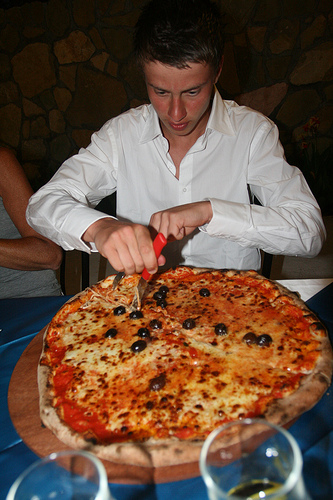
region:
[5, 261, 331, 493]
large pizza with olives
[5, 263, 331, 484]
pizza on wooden serving tray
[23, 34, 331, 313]
young man cutting up pizza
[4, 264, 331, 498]
pizza resting on table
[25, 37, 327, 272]
man wearing white shirt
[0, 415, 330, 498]
glasses on table with blue tablecloth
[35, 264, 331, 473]
thick crust pizza with olives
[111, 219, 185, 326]
knife cutting into pizza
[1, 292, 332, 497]
blue tablecloth on table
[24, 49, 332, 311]
man staring at pizza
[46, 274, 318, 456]
cooked pizza on board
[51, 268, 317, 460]
cheese and olive pizza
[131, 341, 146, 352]
black olive on pizza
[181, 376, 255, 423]
melted cheese on piza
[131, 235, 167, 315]
red plastic and metal knife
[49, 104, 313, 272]
white button down shirt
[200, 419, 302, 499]
glass of wine on table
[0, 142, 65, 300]
person sitting on chair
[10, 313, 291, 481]
brown wooden pizza board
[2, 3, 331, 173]
brown stone covered wall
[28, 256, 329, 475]
a big . yummy pizza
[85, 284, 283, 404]
it has black olives on it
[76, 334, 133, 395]
it also has lots of cheese on it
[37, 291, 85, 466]
the crust is done perfectly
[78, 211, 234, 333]
the man is cutting it with a knife & fork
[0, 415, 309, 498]
two glasses sit on the table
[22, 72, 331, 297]
the man is wearing a long sleeved shirt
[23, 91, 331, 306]
the shirt is white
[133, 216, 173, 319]
the handle of the knife is red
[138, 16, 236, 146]
the man's face appears flushed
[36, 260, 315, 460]
the pizza is huge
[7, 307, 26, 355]
table clothe is blue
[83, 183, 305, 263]
the shirt is white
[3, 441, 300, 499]
glasses are on the table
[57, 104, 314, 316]
the guy is cutting pizza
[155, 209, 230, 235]
left hand is holding fork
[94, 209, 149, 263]
the right hand is holding a knife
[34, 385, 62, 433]
the crust is brown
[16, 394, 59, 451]
the board is wooden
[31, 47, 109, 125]
the wall is made of stones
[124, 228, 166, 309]
A red knife cutting pizza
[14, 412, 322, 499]
Two drink glasses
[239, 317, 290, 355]
Black olives on pizza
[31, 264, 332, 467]
A large pizza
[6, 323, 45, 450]
A brown cutting board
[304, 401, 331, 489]
A blue table cloth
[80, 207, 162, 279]
A right hand holding the knife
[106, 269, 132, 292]
A fork holding pizza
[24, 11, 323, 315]
A young man cutting pizza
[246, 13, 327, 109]
A brown brick wall